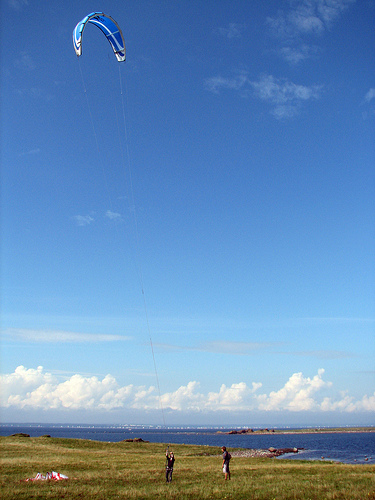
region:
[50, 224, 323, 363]
The sky is blue.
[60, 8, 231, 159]
A kite is flying in the sky.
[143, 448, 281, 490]
People in the field.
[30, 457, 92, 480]
A kite laying in the grass.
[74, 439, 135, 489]
The grass is green and brown.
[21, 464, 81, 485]
The kite is red and white.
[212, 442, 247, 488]
The man is wearing shorts.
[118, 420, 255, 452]
Water is near the open field.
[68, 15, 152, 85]
The kite is blue and white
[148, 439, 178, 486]
A man is managing the kite.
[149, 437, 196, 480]
a man flying a kite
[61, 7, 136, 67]
a large blue and white kite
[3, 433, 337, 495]
a large grassy field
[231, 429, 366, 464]
blue wave less water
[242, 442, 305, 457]
a group of rocks on the shore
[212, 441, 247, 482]
a man standing in the grass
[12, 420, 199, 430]
a bridge crossing the water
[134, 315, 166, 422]
the string of a kite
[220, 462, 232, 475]
a pair of white shorts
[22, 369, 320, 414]
white puffy clouds over the water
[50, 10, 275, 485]
two people flying a large kite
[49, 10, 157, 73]
the large kite is blue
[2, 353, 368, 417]
the clouds are white and fluffy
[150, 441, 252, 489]
two people standing in a field of grass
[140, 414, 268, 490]
two people standing by the water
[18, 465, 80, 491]
a red and white kite on the ground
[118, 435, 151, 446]
large rocks by the water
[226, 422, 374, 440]
an island in the water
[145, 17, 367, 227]
the sky is blue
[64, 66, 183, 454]
the person is holding a line for the kite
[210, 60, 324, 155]
cloud in the blue sky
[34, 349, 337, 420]
many clouds in the sky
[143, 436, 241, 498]
two people in a field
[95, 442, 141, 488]
green grass near people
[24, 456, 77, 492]
two objects laying on the ground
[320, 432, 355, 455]
water next to people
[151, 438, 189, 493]
person flying a kite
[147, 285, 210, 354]
blue sky above the land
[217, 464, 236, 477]
shorts on a person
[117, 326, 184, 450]
kite string in the air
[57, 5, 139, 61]
A large curved kite flying high in the sky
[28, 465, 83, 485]
A red and white kite lying on the ground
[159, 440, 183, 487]
A person flying a kite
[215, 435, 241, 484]
A man watching a kite getting flown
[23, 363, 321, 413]
A row of puffy white clouds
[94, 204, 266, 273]
A brilliant blue sky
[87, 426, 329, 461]
A large expanse of water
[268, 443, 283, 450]
A large rock near the water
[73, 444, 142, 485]
A field of both drying green grass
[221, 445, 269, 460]
Gravel near the waters edge